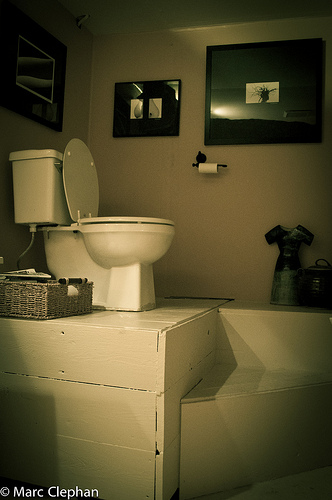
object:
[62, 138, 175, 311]
toilet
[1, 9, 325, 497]
bathroom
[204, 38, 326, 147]
picture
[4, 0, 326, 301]
wall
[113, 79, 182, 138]
frame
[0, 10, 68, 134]
pike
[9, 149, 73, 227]
tank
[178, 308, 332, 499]
stairs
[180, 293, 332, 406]
up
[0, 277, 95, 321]
basket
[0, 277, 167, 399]
ground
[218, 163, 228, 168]
handle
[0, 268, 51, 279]
magazine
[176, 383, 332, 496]
wood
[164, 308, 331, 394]
riser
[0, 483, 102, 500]
name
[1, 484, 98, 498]
photographer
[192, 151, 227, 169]
holder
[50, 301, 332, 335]
floor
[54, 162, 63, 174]
lever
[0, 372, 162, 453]
drawer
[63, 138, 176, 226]
seat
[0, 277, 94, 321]
reeds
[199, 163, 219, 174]
tissue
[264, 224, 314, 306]
dress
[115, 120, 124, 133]
black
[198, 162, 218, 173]
roll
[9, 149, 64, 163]
cover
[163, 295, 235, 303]
edge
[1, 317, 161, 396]
part